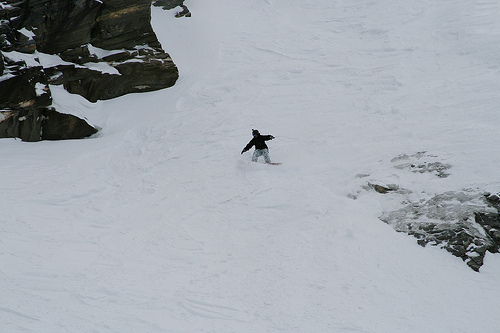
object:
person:
[242, 126, 282, 163]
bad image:
[240, 129, 274, 164]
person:
[225, 124, 287, 171]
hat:
[240, 121, 268, 138]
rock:
[0, 0, 192, 142]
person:
[240, 127, 275, 162]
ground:
[383, 110, 410, 132]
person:
[230, 125, 276, 166]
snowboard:
[263, 160, 280, 166]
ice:
[356, 151, 498, 271]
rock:
[1, 0, 497, 330]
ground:
[218, 19, 495, 146]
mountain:
[0, 2, 497, 330]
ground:
[361, 152, 415, 201]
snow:
[3, 242, 248, 330]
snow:
[75, 153, 251, 311]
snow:
[210, 197, 380, 316]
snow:
[206, 214, 381, 328]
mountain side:
[5, 7, 497, 332]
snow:
[143, 12, 374, 332]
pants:
[248, 147, 274, 163]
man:
[238, 126, 279, 168]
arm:
[262, 135, 275, 142]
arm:
[241, 140, 252, 155]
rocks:
[1, 1, 193, 143]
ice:
[388, 174, 499, 266]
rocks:
[395, 194, 497, 254]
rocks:
[0, 0, 177, 142]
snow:
[0, 3, 498, 330]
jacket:
[240, 135, 270, 150]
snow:
[66, 263, 268, 332]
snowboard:
[248, 147, 283, 164]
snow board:
[243, 150, 310, 181]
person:
[229, 115, 292, 175]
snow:
[286, 58, 456, 154]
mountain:
[363, 151, 495, 286]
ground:
[187, 204, 441, 318]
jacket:
[236, 125, 291, 154]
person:
[206, 99, 303, 172]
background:
[0, 0, 496, 121]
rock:
[356, 161, 490, 291]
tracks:
[2, 253, 225, 325]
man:
[218, 107, 285, 179]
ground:
[269, 40, 498, 124]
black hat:
[241, 125, 265, 141]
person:
[197, 101, 325, 197]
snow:
[159, 27, 388, 133]